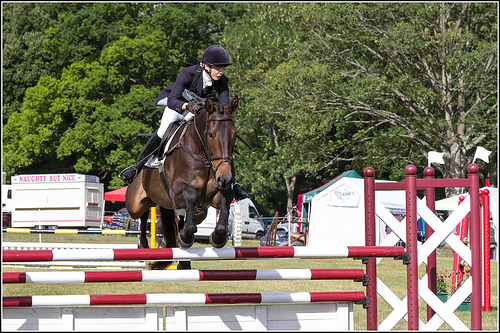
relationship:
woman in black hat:
[149, 22, 235, 167] [195, 43, 263, 82]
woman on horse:
[149, 22, 235, 167] [144, 121, 235, 248]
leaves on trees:
[394, 49, 407, 59] [350, 17, 499, 159]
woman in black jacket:
[149, 22, 235, 167] [173, 78, 241, 113]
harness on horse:
[206, 145, 237, 159] [144, 121, 235, 248]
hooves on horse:
[171, 218, 259, 258] [144, 121, 235, 248]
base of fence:
[121, 315, 280, 328] [17, 243, 376, 332]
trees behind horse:
[350, 17, 499, 159] [144, 121, 235, 248]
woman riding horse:
[149, 22, 235, 167] [144, 121, 235, 248]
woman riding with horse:
[149, 22, 235, 167] [144, 121, 235, 248]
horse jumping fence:
[144, 121, 235, 248] [17, 243, 376, 332]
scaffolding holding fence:
[355, 171, 472, 319] [17, 243, 376, 332]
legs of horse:
[159, 181, 246, 243] [144, 121, 235, 248]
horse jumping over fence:
[144, 121, 235, 248] [17, 243, 376, 332]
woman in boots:
[149, 22, 235, 167] [129, 139, 155, 165]